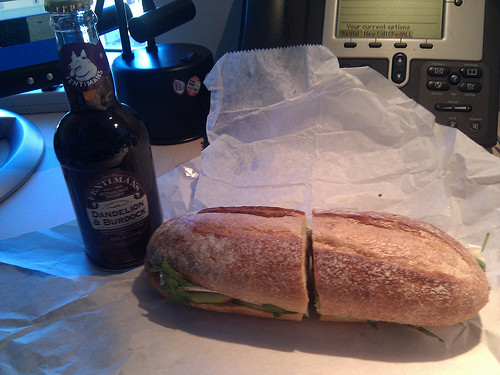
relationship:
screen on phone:
[336, 3, 439, 38] [241, 4, 499, 149]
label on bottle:
[73, 166, 154, 238] [43, 2, 166, 265]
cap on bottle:
[43, 1, 95, 11] [43, 2, 166, 265]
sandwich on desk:
[140, 210, 496, 322] [7, 95, 493, 249]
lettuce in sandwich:
[151, 264, 204, 294] [140, 210, 496, 322]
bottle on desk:
[43, 2, 166, 265] [7, 95, 493, 249]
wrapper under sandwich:
[0, 53, 499, 373] [140, 210, 496, 322]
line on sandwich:
[296, 215, 330, 320] [140, 210, 496, 322]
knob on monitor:
[27, 77, 37, 86] [1, 1, 95, 90]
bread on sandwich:
[312, 209, 488, 324] [140, 210, 496, 322]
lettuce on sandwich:
[151, 264, 204, 294] [140, 210, 496, 322]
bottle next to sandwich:
[43, 2, 166, 265] [140, 210, 496, 322]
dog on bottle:
[64, 50, 103, 83] [43, 2, 166, 265]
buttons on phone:
[423, 60, 491, 98] [241, 4, 499, 149]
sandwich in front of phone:
[140, 210, 496, 322] [241, 4, 499, 149]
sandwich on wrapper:
[140, 210, 496, 322] [0, 53, 499, 373]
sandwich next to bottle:
[140, 210, 496, 322] [43, 2, 166, 265]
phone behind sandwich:
[241, 4, 499, 149] [140, 210, 496, 322]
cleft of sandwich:
[296, 215, 330, 320] [140, 210, 496, 322]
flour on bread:
[333, 263, 399, 292] [312, 209, 488, 324]